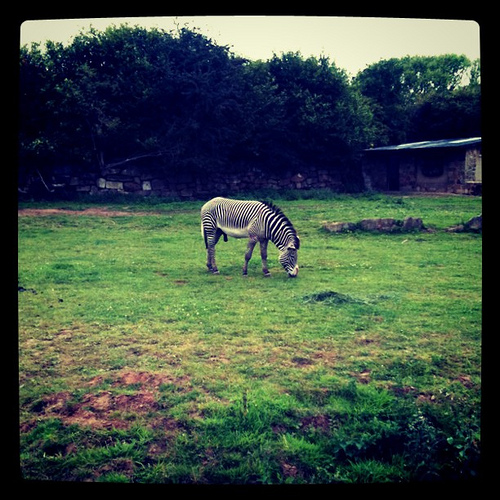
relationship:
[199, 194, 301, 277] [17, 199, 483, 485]
zebra eating grass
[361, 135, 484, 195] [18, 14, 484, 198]
building on right side of background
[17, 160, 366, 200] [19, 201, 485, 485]
fence at back of field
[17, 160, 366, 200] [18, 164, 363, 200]
fence made of stone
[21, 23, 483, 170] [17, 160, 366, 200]
trees behind fence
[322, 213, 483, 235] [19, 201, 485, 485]
rocks in middle of field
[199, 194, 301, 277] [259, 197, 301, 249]
zebra has mane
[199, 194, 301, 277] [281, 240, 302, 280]
zebra has head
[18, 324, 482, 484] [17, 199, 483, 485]
patches on grass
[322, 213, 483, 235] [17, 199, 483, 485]
rocks in grass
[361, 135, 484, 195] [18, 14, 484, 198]
building in background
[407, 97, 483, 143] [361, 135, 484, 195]
tree next to building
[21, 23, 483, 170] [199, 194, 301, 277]
trees behind zebra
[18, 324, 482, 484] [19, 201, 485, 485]
patches on field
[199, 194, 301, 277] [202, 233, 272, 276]
zebra has legs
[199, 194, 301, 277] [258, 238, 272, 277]
zebra has front leg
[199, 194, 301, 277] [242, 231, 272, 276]
zebra has front legs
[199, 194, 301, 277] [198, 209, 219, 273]
zebra has rear legs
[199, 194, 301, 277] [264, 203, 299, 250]
zebra has neck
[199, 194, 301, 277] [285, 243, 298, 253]
zebra has ear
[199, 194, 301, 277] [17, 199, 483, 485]
zebra standing on top of grass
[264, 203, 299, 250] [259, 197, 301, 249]
neck has mane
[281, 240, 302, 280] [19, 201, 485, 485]
head bending towards field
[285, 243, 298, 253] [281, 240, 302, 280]
ear on side of head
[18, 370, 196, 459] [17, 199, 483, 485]
dirt in grass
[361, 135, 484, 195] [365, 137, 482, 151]
building has roof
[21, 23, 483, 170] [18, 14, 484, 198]
trees in background